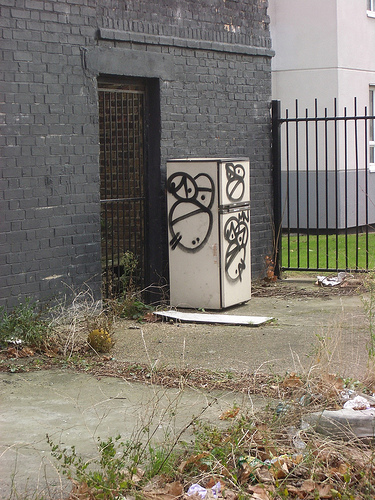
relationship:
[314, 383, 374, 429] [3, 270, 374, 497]
trash on sidewalk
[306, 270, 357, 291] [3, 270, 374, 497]
trash on sidewalk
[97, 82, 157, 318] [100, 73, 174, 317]
grate on door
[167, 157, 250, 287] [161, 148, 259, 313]
graffiti on refrigerator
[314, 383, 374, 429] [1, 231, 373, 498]
trash on ground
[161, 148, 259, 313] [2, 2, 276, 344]
refrigerator against wall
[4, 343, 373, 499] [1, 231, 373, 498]
leaves on ground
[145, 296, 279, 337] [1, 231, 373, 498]
cardboard on ground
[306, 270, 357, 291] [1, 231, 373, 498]
trash on ground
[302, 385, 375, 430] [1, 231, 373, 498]
bag on ground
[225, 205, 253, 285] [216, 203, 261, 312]
graffiti on door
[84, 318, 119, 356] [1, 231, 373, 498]
ball on ground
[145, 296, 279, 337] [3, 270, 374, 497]
board on sidewalk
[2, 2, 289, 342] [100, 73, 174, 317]
building has door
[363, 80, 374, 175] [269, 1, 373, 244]
window on building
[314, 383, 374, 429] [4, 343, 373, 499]
trash mixed with leaves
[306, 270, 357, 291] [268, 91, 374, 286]
trash under gate